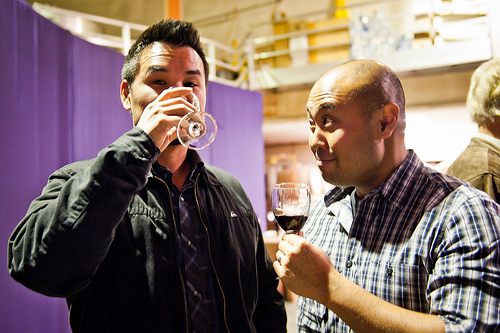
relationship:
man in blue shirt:
[6, 17, 287, 332] [153, 157, 210, 330]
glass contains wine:
[271, 182, 308, 281] [275, 214, 307, 233]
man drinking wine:
[6, 17, 287, 332] [277, 217, 303, 222]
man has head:
[270, 57, 498, 331] [285, 52, 440, 174]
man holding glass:
[270, 57, 498, 331] [271, 178, 315, 237]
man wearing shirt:
[270, 57, 498, 331] [240, 150, 496, 310]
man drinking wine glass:
[270, 57, 498, 331] [270, 179, 315, 236]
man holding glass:
[270, 57, 498, 331] [271, 182, 310, 281]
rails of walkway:
[247, 36, 362, 58] [212, 25, 446, 78]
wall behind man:
[21, 46, 77, 124] [6, 17, 287, 332]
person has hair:
[445, 56, 499, 204] [464, 58, 499, 127]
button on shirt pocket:
[380, 264, 398, 281] [367, 249, 416, 300]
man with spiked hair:
[6, 17, 287, 332] [129, 16, 206, 58]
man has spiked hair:
[6, 17, 287, 332] [119, 16, 211, 85]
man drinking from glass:
[6, 17, 287, 332] [132, 86, 237, 159]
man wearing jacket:
[270, 57, 498, 331] [47, 140, 287, 307]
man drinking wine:
[6, 17, 287, 332] [87, 24, 264, 314]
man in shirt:
[270, 57, 498, 331] [302, 187, 493, 329]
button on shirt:
[344, 259, 352, 269] [306, 149, 498, 331]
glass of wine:
[271, 182, 310, 281] [262, 168, 344, 235]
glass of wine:
[271, 182, 310, 281] [275, 215, 307, 230]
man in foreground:
[100, 29, 225, 191] [17, 11, 482, 283]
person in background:
[430, 49, 498, 186] [6, 5, 481, 267]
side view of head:
[288, 45, 416, 197] [265, 42, 459, 242]